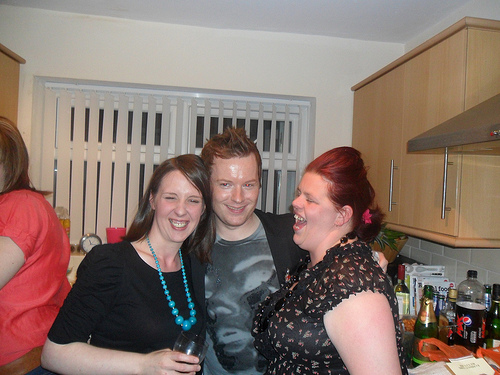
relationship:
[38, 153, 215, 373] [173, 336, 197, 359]
lady holding glass